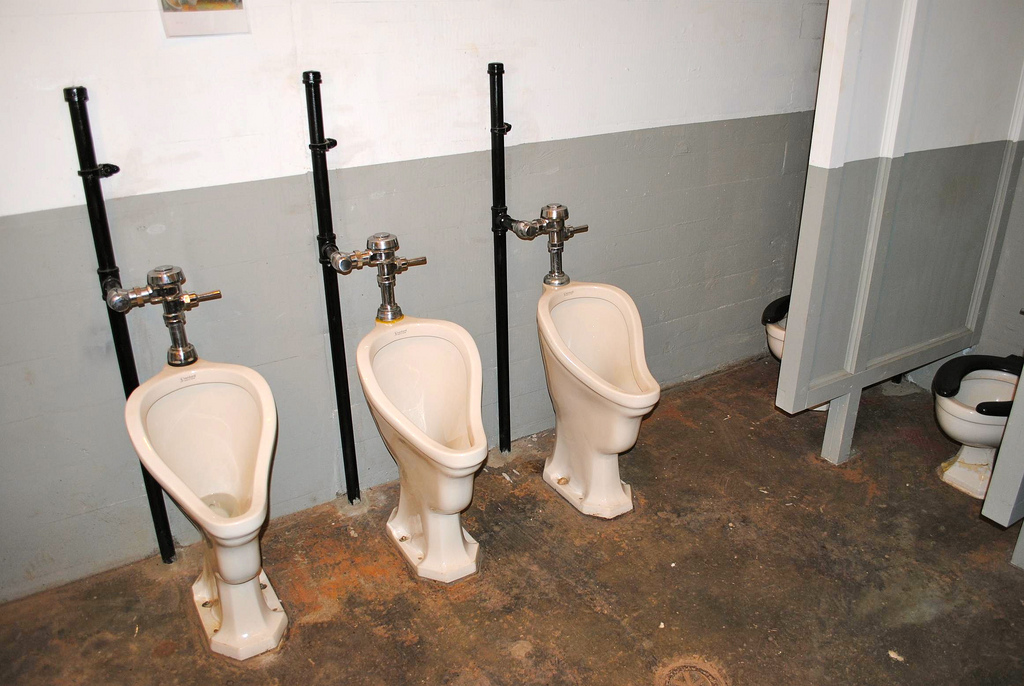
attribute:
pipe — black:
[266, 65, 393, 509]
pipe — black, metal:
[297, 63, 384, 513]